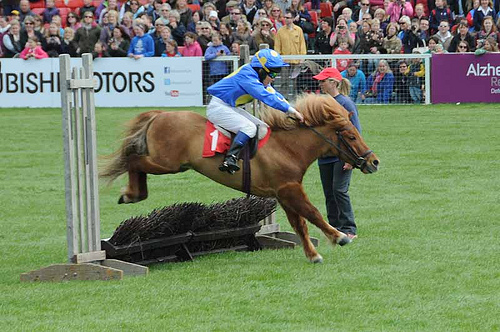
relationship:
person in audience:
[177, 28, 204, 55] [1, 0, 498, 102]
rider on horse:
[207, 47, 306, 176] [98, 90, 381, 266]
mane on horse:
[254, 93, 348, 129] [98, 90, 381, 266]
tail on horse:
[99, 110, 157, 182] [98, 90, 381, 266]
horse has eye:
[98, 90, 381, 266] [347, 131, 357, 143]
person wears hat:
[309, 67, 363, 247] [311, 65, 344, 81]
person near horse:
[309, 67, 363, 247] [98, 90, 381, 266]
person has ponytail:
[309, 67, 363, 247] [338, 74, 354, 95]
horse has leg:
[98, 90, 381, 266] [116, 169, 140, 208]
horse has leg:
[98, 90, 381, 266] [136, 170, 150, 204]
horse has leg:
[98, 90, 381, 266] [275, 180, 354, 250]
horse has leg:
[98, 90, 381, 266] [282, 212, 327, 264]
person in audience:
[397, 14, 412, 38] [1, 0, 498, 102]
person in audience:
[18, 35, 51, 60] [1, 0, 498, 102]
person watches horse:
[328, 20, 355, 45] [98, 90, 381, 266]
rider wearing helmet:
[207, 47, 306, 176] [250, 46, 290, 69]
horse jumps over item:
[98, 90, 381, 266] [107, 190, 276, 259]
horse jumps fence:
[98, 90, 381, 266] [23, 50, 320, 280]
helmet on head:
[250, 46, 290, 69] [253, 65, 284, 88]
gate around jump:
[59, 50, 110, 259] [107, 190, 276, 259]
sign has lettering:
[1, 57, 204, 108] [0, 70, 158, 96]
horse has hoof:
[98, 90, 381, 266] [339, 233, 352, 248]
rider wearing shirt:
[207, 47, 306, 176] [204, 64, 289, 114]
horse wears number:
[98, 90, 381, 266] [209, 126, 224, 154]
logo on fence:
[163, 64, 173, 74] [0, 47, 500, 108]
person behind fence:
[204, 33, 232, 80] [23, 50, 320, 280]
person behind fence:
[397, 14, 412, 38] [0, 47, 500, 108]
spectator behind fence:
[382, 21, 402, 52] [0, 47, 500, 108]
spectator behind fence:
[72, 10, 102, 54] [0, 47, 500, 108]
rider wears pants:
[207, 47, 306, 176] [207, 96, 268, 140]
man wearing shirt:
[274, 9, 312, 95] [272, 25, 308, 62]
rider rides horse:
[207, 47, 306, 176] [98, 90, 381, 266]